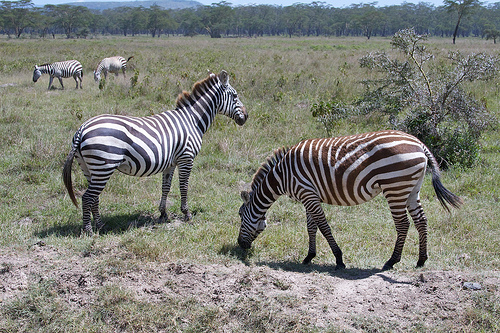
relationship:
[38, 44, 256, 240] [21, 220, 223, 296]
zebra in field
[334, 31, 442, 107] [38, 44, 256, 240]
dirt on zebra